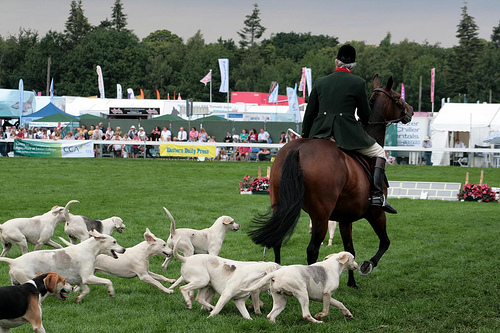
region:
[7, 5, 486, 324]
Horse jockey, horse and dog at a horsepark.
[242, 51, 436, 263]
Jockey riding a dark brown horse.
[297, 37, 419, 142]
Horse jockey wearing a black jacket.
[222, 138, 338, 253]
Long black horsetail.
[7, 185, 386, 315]
Pack of white dogs running behind a horse.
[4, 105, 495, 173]
Audience at a horse park.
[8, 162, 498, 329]
Large green turf of a horse park.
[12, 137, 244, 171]
Vinyl outdoor banners hanging over a railing.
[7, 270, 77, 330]
Black and brown dog with it mouth open.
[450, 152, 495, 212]
A bunch of flowers on the ground at a horse park.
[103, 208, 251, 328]
White dogs running on grass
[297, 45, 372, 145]
Man wearing green jacket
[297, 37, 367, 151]
Man wearing black cap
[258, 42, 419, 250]
Man riding brown horse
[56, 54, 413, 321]
White dogs following man on horse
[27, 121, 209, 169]
Several people spectating behind barrier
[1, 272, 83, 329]
Black and brown beagle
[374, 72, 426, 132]
Brown horse facing away from camera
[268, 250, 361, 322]
White dog with gray spot running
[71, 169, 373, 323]
Several white dogs running behind horse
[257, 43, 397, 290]
Man on a brown horse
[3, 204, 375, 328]
Dogs following the horse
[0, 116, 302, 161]
Large crowd watching the sport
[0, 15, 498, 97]
Many trees in background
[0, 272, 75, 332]
Dog with brown, black, and white fur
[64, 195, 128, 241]
White dog with black spot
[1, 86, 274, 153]
People standing under a tent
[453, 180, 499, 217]
Bush of flowers on the ground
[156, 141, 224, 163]
Banner for advertisement near people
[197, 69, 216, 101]
Flag on a pole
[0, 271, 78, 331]
dog running behing horse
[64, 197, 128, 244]
white dog running behing horse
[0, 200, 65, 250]
white dog running behing horse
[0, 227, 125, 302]
white dog running behing horsewhite dog running behing horse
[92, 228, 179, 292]
white dog running behing horse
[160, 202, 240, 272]
white dog running behing horse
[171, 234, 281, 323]
white dog running behing horse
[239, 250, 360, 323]
white dog running behing horse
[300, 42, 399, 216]
man sitting on brown horse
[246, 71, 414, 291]
brown horse is race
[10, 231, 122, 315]
a white dog is running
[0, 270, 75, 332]
a brown, black, and white dog is running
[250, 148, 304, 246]
tail of a horse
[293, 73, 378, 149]
a man's green jacket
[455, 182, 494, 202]
a bushel of pink flowers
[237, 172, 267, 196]
a bushel of pink flowers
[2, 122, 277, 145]
a crowd of people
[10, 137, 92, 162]
a green and white banner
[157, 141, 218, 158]
a yellow and blue banner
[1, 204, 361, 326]
a group of white dogs